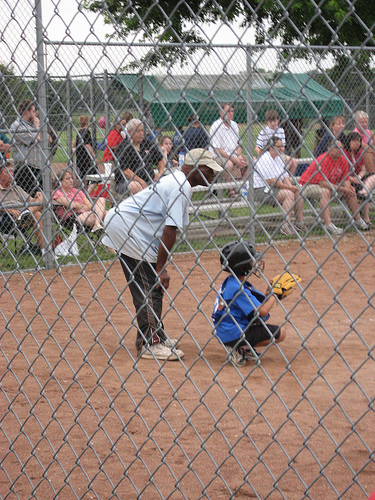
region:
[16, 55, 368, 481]
People playing baseball.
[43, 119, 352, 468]
A metal fence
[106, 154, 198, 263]
A man is wearing a white shirt.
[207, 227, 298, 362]
A boy is playing the catcher.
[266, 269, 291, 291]
The boy wears a glove on his hand.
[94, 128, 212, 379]
The man is leaning over.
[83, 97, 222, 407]
The man is playing umpire.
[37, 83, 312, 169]
People are watching the game.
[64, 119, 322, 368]
The people are in the infield.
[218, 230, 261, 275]
The boy is wearing a black helmet.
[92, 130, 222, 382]
man wearing a cap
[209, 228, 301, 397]
the kid is wearing a glove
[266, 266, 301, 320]
the glove is yellow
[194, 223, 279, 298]
the helmet is black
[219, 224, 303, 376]
the kid is wearing a helmet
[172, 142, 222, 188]
the cap is beige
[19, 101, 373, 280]
the people outside the fence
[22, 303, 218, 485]
the fence is wired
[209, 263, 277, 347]
the shirt is blue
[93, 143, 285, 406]
a man behind the catcher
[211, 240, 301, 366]
the boy crouching on the ground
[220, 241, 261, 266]
the helmet on the catcher's head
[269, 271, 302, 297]
the catcher's mitt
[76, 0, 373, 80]
the leaves of the tree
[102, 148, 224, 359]
the man standing behind the catcher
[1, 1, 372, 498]
the chain link fence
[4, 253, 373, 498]
the dirt on the ground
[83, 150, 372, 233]
the white bleachers outside of the chain link fence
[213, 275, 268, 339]
a short sleeved blue shirt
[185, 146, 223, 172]
the hat on the man's head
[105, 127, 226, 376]
man wearing a t shirt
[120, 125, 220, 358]
man wearing jogging pants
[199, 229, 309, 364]
boy wearing a helmet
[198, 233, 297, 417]
boy wearing a glove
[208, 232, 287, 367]
boy wearing blue t shirt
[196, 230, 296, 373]
boy wearing blue shorts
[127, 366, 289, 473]
fence around a field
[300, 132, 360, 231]
man wearing red t shirt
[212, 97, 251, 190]
man wearing a white shirt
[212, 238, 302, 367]
boy waiting to catch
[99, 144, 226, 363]
man standing behind catcher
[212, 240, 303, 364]
boy wearing a catcher's helmet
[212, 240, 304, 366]
boy wearing a baseball glove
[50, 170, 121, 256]
woman sitting on chair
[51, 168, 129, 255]
woman has her legs crossed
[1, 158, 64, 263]
man sitting on chair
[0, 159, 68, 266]
man has his legs crossed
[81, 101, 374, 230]
spectators sitting on bleachers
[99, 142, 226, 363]
man hunched over behind boy